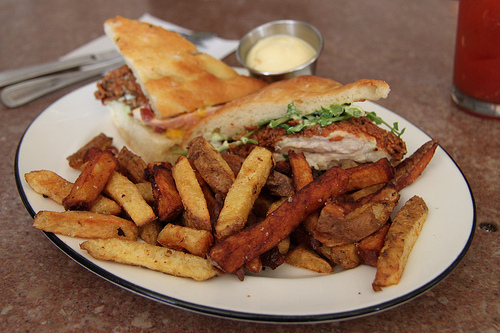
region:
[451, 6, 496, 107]
a glass on the table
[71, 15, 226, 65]
a napkin on the table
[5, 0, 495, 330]
a table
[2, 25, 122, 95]
silverware on the napkin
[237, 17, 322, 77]
a cup of sauce on the plate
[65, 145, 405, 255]
french fries on the plate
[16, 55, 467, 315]
a plate of food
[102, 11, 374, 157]
a sandwich on the plate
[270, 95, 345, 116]
the lettuce on the sandwich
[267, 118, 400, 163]
the meat on the sandwich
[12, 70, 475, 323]
a white plate with a black border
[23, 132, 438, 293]
homemade fries with potato skin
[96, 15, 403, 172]
a sandwich on a white plate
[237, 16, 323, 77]
a small metal container with white sauce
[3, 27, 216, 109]
utensils on a table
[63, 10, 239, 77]
a white napkin on a table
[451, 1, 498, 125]
a glass of red juice on a table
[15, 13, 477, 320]
a plate with fries and a sandwich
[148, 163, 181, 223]
a deep fried French fry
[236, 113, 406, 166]
chicken in a sandwich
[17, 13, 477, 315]
chicken sandwich and fries on a plate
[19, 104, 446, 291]
fries with seasoning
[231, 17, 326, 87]
dipping sauce in a metal tin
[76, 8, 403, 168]
chicken sandwich cut in half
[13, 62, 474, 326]
white plate with dark blue rim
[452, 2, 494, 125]
glass with dark orange drink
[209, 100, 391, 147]
lettuce on the sandwich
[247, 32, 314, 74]
light yellow sauce in a small container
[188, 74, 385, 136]
triangular shaped bread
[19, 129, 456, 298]
a pile of fries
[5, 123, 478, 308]
fries on the side of a plate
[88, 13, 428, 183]
sandwich on the plate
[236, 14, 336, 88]
white sauce in the silver container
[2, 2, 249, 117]
silverware on a napkin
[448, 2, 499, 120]
liquid in a glass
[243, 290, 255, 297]
speck on the plate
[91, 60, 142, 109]
meat hanging off the sandwich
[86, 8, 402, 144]
bread on top of the sandwich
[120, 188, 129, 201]
black speck on the fry